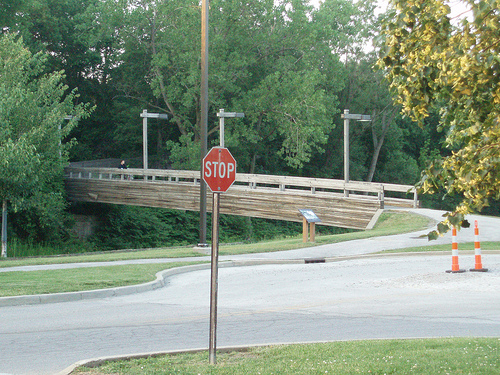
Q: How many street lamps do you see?
A: I see three street lamps.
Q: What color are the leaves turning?
A: Yellow.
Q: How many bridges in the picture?
A: One.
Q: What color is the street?
A: Grey.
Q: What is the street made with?
A: Concrete.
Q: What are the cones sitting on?
A: The street.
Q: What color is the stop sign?
A: Red and white.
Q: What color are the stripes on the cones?
A: White.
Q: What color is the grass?
A: Green.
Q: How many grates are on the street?
A: One.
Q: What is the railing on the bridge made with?
A: Wood.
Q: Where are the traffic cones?
A: Street.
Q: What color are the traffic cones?
A: Orange and white.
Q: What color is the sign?
A: Red.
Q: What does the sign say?
A: STOP.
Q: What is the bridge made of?
A: Wood.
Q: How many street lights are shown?
A: 3.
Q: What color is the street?
A: Gray.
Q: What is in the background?
A: Trees.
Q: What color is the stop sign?
A: Red.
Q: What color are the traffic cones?
A: Orange and white.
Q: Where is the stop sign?
A: On a pole.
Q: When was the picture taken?
A: Daytime.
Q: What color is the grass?
A: Green.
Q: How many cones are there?
A: Two.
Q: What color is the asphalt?
A: Gray.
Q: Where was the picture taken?
A: On a roadway.